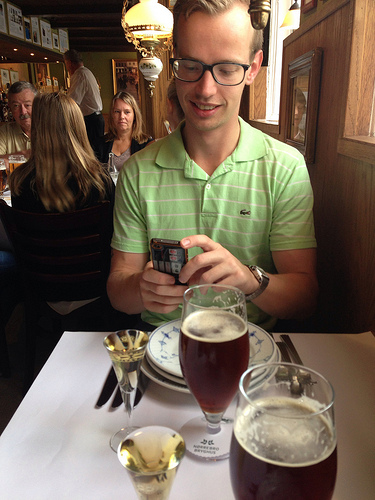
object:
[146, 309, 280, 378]
plate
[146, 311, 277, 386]
plate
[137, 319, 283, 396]
plate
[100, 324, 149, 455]
glass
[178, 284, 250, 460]
glass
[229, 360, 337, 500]
glass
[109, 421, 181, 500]
glass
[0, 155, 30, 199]
glass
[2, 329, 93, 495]
table cloth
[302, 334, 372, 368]
table cloth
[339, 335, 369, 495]
table cloth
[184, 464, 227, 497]
table cloth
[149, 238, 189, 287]
cell phone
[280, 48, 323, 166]
picture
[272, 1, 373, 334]
wall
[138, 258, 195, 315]
hand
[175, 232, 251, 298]
hand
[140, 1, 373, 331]
wall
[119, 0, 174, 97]
light fixture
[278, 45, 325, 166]
wooden frame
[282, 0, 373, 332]
wall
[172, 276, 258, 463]
glass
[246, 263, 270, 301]
watch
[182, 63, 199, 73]
eye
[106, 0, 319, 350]
person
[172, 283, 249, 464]
beer glass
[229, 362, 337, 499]
beer glass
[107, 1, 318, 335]
man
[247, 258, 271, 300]
watch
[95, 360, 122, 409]
knife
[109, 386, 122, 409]
knife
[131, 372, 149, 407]
knife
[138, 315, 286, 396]
plates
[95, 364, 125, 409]
butter knife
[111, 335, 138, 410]
butter knife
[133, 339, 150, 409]
butter knife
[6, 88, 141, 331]
woman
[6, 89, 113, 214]
hair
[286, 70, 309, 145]
mirror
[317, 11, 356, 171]
wall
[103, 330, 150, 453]
cup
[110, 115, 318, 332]
shirt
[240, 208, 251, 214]
alligator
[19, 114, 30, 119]
mustache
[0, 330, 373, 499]
table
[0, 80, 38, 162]
man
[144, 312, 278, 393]
plate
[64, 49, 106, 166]
man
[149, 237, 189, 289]
phone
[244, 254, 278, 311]
wrist